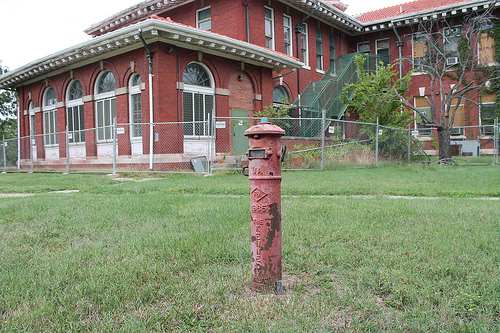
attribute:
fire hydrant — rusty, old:
[235, 114, 291, 303]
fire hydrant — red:
[239, 111, 293, 298]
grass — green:
[133, 211, 389, 331]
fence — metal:
[6, 116, 495, 165]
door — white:
[175, 56, 220, 161]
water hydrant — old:
[233, 111, 296, 296]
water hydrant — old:
[237, 109, 293, 296]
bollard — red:
[235, 113, 291, 296]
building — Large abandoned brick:
[0, 2, 481, 211]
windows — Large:
[181, 62, 221, 132]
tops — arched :
[180, 67, 216, 81]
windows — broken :
[407, 35, 433, 76]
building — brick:
[4, 1, 482, 160]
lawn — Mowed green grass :
[8, 161, 478, 331]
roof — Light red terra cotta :
[0, 5, 480, 85]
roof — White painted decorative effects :
[4, 9, 483, 68]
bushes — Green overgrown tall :
[337, 35, 483, 155]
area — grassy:
[9, 168, 484, 324]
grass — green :
[10, 167, 480, 330]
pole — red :
[229, 114, 291, 294]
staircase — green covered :
[292, 50, 372, 141]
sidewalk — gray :
[4, 180, 106, 196]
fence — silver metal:
[8, 104, 415, 172]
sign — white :
[413, 80, 428, 97]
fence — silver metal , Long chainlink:
[18, 110, 481, 165]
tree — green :
[336, 17, 476, 175]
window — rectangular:
[263, 3, 275, 52]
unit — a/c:
[445, 57, 460, 64]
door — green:
[230, 106, 250, 153]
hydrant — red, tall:
[244, 120, 286, 295]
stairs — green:
[281, 50, 357, 137]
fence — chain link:
[22, 113, 412, 173]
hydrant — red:
[241, 120, 292, 297]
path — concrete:
[11, 185, 484, 207]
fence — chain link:
[18, 112, 407, 179]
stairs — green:
[287, 53, 369, 134]